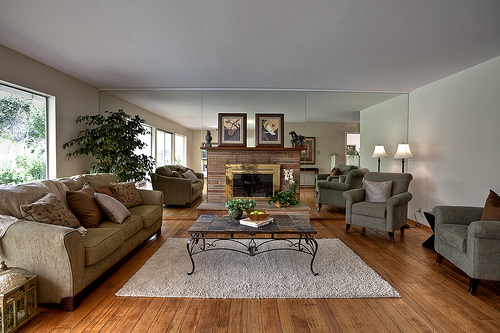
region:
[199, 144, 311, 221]
Modern style fireplace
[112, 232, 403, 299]
Cream colored area rug in middle of a room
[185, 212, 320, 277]
Stone tiled top table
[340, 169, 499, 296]
Two green single person couch chairs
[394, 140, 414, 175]
Floor lamp with a white shade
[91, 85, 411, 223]
Wall covered from floor to ceiling with mirrors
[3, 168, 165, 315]
Tan colored sofa couch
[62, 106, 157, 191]
Tree in corner of a room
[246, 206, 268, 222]
Brown basket with green contents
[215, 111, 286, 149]
Two framed peices of artwork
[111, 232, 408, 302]
a white area on a wood floor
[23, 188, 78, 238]
a pillow on a sofa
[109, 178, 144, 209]
a pillow on a sofa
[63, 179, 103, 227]
a pillow on a sofa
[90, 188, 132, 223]
a pillow on a sofa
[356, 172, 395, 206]
a pillow on a chaire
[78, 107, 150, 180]
a house plant by a sofa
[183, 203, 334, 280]
a coffee table on a white carpet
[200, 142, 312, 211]
a brick fire place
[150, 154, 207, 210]
a sofa in by a window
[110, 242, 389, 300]
white rug under table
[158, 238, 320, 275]
black legs on coffee table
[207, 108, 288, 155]
two pictures on the wall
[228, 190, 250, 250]
green plant on the table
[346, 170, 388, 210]
gray pillow on the chair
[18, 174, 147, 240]
four pillows on the sofa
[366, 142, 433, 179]
two white lamps behind chair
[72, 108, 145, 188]
large leafy plant behind sofa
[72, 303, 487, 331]
floor is made of hardwood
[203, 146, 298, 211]
fireplace is made of brick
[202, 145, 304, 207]
large stone fireplace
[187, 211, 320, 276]
metal and stone coffee table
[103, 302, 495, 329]
pretty brown wooden floor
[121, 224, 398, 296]
off white shag carpet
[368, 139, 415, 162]
two lampshades against wall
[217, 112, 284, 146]
framed paintings on fireplace mantel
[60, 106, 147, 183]
a green leafy tree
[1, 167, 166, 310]
tan couch with pillows on it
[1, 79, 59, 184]
large clear window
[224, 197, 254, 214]
a potted plant with green leaves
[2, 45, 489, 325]
The room is inside somebody's house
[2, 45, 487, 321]
The room has nice comfortable furniture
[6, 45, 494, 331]
The room is furnished very nice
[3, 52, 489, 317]
The room has a nice sofa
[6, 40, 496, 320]
The room has a very big fireplace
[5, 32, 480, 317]
The room has a big coffee table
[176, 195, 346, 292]
A coffee table is sitting on a rug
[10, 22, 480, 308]
There are plants inside a room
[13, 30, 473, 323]
The room has a very big mirror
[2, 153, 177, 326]
The sofa has many nice pillows